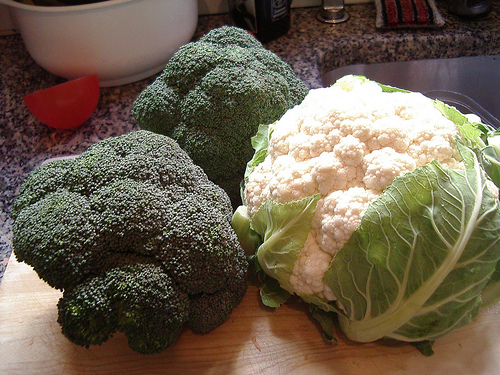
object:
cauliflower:
[231, 74, 500, 346]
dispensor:
[313, 0, 348, 24]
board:
[4, 216, 498, 372]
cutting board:
[0, 227, 498, 374]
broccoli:
[129, 26, 311, 205]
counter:
[1, 1, 500, 375]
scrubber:
[368, 0, 446, 34]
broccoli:
[10, 123, 251, 354]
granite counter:
[1, 2, 500, 258]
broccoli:
[6, 69, 283, 345]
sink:
[311, 44, 497, 132]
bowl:
[12, 1, 198, 87]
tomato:
[23, 75, 97, 130]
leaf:
[329, 130, 498, 349]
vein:
[395, 187, 485, 330]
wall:
[437, 51, 494, 111]